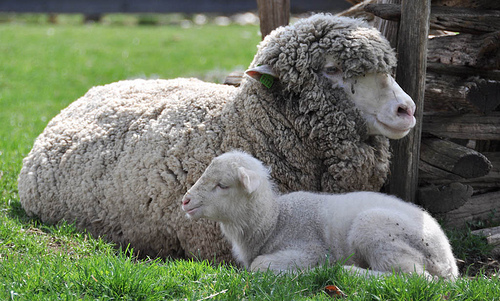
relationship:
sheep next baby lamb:
[268, 16, 410, 179] [172, 143, 466, 295]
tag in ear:
[258, 74, 281, 97] [252, 67, 273, 78]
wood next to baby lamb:
[429, 34, 484, 116] [172, 147, 464, 291]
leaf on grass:
[320, 281, 346, 297] [363, 285, 381, 298]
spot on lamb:
[391, 220, 402, 232] [177, 150, 468, 285]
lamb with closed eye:
[177, 150, 468, 285] [214, 179, 230, 192]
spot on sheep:
[391, 220, 402, 232] [268, 16, 410, 179]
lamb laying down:
[177, 150, 468, 285] [226, 260, 447, 279]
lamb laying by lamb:
[177, 150, 468, 285] [268, 16, 410, 179]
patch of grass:
[55, 49, 84, 66] [363, 285, 381, 298]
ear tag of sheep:
[252, 67, 273, 78] [268, 16, 410, 179]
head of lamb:
[189, 149, 262, 234] [177, 150, 468, 285]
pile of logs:
[441, 137, 494, 175] [435, 36, 490, 158]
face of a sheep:
[327, 41, 414, 153] [268, 16, 410, 179]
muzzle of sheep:
[381, 95, 418, 146] [268, 16, 410, 179]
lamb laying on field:
[177, 150, 468, 285] [142, 260, 186, 287]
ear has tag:
[252, 67, 273, 78] [258, 74, 281, 97]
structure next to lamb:
[413, 6, 424, 195] [177, 150, 468, 285]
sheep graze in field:
[268, 16, 410, 179] [142, 260, 186, 287]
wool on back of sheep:
[127, 90, 204, 131] [268, 16, 410, 179]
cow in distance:
[81, 10, 100, 23] [106, 16, 135, 31]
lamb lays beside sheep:
[177, 150, 468, 285] [268, 16, 410, 179]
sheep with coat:
[268, 16, 410, 179] [91, 127, 171, 192]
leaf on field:
[312, 275, 348, 296] [0, 16, 243, 301]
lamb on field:
[177, 150, 468, 285] [0, 16, 243, 301]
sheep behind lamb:
[268, 16, 410, 179] [177, 150, 468, 285]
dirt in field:
[31, 229, 88, 266] [0, 16, 243, 301]